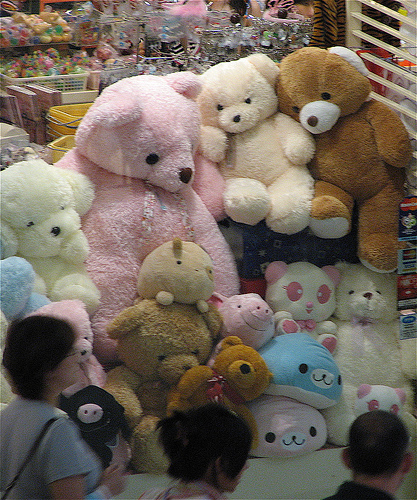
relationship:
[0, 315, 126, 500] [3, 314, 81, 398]
individual has head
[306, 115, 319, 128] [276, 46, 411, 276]
nose on bear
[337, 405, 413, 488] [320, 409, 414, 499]
head of individual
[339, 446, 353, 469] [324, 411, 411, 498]
ear of man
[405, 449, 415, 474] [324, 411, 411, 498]
ear of man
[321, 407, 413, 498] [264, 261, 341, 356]
individual looking at stuffed animal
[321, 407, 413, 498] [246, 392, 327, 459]
individual looking at toy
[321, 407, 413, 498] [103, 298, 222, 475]
individual looking at teddy bear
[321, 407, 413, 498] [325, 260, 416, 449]
individual looking at teddy bear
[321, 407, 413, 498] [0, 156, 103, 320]
individual looking at toy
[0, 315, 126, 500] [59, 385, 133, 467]
individual looking at pig doll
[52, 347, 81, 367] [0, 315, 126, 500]
glasses on individual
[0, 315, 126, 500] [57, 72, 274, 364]
individual looking bear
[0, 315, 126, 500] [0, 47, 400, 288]
individual looking at teddy bears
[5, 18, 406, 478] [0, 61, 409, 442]
store window display of stuffed animals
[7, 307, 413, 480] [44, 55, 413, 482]
people walk past toys